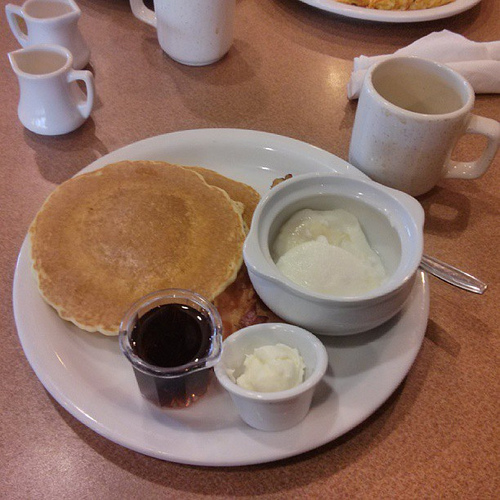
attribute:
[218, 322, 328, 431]
container — white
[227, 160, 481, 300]
spoon — handle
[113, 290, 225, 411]
glass — syrup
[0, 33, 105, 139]
ceramic pitcher — small , white , ceramic 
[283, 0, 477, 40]
plate — white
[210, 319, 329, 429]
bowl — white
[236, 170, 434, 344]
pot — white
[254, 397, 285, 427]
bowl — small, white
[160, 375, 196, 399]
bowl — white, small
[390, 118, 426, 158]
coffee mug — empty, white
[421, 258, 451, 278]
handle — silver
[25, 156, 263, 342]
pancakes — stacked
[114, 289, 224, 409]
syrup — maple, sticky, brown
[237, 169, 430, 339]
bowl — large, white, round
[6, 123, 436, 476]
plate — white, round, large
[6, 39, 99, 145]
pitcher — white, small, cream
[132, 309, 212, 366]
syrup — maple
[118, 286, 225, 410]
container — clear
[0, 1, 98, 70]
pitcher — white, cream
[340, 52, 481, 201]
coffee cup — white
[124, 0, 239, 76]
coffee cup — white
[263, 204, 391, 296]
eggs — poached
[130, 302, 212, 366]
syrup — maple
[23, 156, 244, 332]
food — brown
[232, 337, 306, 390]
stuff — white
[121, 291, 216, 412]
cup — plastic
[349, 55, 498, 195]
coffe cup — white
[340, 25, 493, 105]
napkin — white